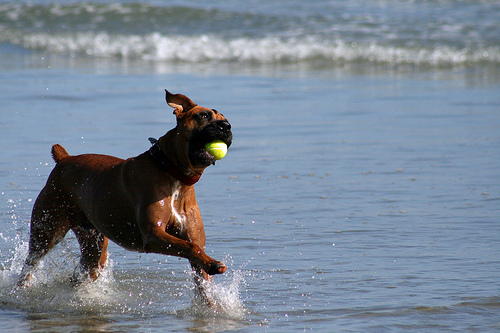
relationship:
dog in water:
[47, 90, 245, 309] [313, 138, 429, 239]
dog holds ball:
[47, 90, 245, 309] [195, 126, 226, 166]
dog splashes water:
[47, 90, 245, 309] [313, 138, 429, 239]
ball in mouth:
[195, 126, 226, 166] [201, 132, 221, 162]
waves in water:
[83, 9, 499, 102] [313, 138, 429, 239]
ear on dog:
[167, 82, 209, 120] [47, 90, 245, 309]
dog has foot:
[47, 90, 245, 309] [198, 256, 225, 282]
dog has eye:
[47, 90, 245, 309] [194, 109, 212, 138]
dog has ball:
[47, 90, 245, 309] [195, 126, 226, 166]